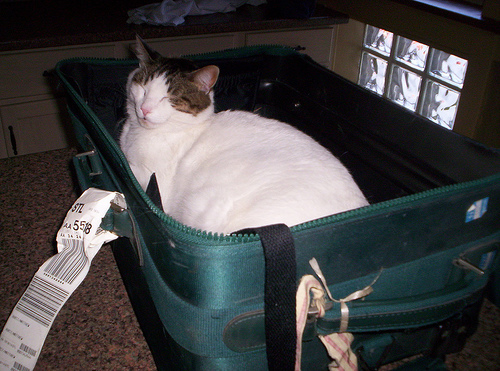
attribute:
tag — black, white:
[57, 174, 95, 262]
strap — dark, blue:
[328, 275, 444, 355]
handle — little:
[4, 124, 21, 154]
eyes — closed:
[131, 76, 179, 111]